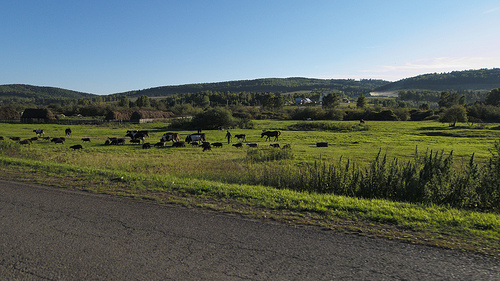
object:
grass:
[0, 118, 500, 257]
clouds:
[354, 0, 500, 80]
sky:
[0, 0, 500, 96]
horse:
[260, 130, 281, 142]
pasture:
[0, 116, 500, 262]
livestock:
[0, 127, 291, 152]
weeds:
[236, 143, 500, 214]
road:
[0, 178, 500, 281]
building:
[20, 106, 56, 124]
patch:
[34, 148, 249, 176]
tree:
[189, 106, 240, 131]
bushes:
[279, 104, 349, 120]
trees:
[0, 66, 500, 122]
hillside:
[366, 66, 500, 112]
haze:
[328, 27, 499, 81]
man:
[224, 130, 232, 145]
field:
[0, 119, 500, 258]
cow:
[185, 133, 207, 145]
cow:
[159, 134, 177, 146]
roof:
[22, 107, 53, 118]